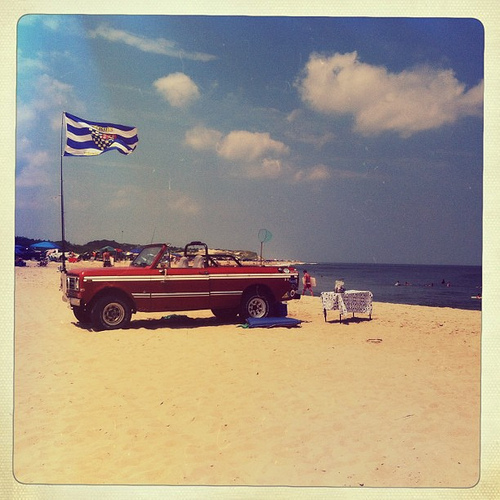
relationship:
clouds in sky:
[158, 65, 215, 120] [22, 20, 467, 278]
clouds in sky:
[209, 111, 345, 183] [22, 20, 467, 278]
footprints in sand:
[56, 338, 366, 464] [16, 262, 483, 486]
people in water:
[390, 275, 455, 287] [270, 258, 491, 310]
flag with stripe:
[61, 110, 141, 160] [65, 125, 135, 154]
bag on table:
[333, 277, 346, 294] [318, 288, 373, 323]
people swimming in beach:
[302, 269, 313, 299] [14, 259, 479, 477]